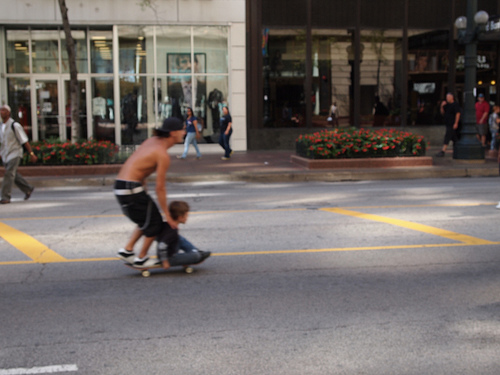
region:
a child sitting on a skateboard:
[141, 198, 210, 281]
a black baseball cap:
[153, 112, 187, 137]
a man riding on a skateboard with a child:
[114, 110, 216, 277]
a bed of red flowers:
[290, 121, 425, 174]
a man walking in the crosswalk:
[0, 100, 35, 202]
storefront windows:
[4, 25, 236, 156]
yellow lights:
[472, 73, 494, 89]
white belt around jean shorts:
[114, 180, 145, 199]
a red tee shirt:
[471, 96, 490, 121]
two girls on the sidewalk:
[180, 104, 235, 160]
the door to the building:
[34, 75, 93, 145]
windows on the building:
[120, 34, 226, 126]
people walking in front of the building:
[181, 101, 248, 157]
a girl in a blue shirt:
[178, 112, 198, 152]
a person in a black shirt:
[210, 100, 242, 158]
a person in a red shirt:
[468, 95, 491, 135]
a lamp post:
[451, 20, 482, 155]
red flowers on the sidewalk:
[293, 128, 423, 160]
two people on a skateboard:
[108, 111, 205, 270]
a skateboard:
[128, 260, 193, 270]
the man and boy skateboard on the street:
[110, 100, 216, 284]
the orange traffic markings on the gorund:
[321, 195, 485, 255]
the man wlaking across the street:
[1, 98, 39, 207]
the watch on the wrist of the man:
[27, 149, 37, 160]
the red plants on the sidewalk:
[296, 127, 428, 163]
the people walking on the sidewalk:
[182, 100, 234, 164]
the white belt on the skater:
[111, 181, 146, 198]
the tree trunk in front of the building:
[51, 0, 83, 147]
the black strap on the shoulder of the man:
[7, 121, 19, 146]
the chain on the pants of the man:
[133, 195, 155, 237]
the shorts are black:
[114, 180, 154, 240]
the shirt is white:
[2, 121, 28, 161]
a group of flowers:
[303, 123, 428, 162]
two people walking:
[177, 100, 237, 160]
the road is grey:
[5, 173, 497, 364]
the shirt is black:
[220, 115, 231, 132]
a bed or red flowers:
[23, 140, 118, 166]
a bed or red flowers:
[287, 125, 427, 155]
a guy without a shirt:
[111, 115, 181, 267]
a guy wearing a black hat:
[110, 115, 185, 265]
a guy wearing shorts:
[110, 111, 185, 261]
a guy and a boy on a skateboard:
[110, 115, 223, 275]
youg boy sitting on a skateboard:
[124, 199, 209, 276]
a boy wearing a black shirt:
[154, 199, 210, 273]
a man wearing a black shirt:
[438, 93, 462, 156]